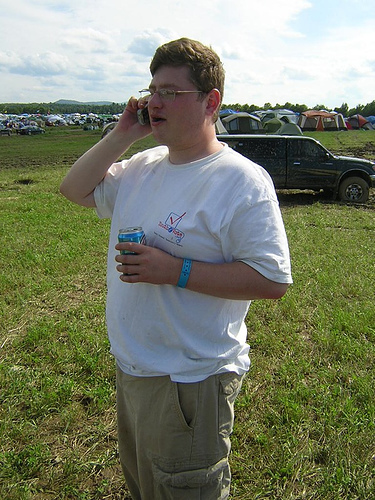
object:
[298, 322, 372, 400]
grass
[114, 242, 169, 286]
hand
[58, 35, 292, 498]
man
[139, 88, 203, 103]
glasses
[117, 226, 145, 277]
can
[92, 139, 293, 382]
shirt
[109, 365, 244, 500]
pants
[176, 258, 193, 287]
wrist band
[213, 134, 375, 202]
truck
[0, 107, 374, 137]
tents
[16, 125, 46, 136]
car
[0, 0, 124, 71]
cloud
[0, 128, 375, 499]
grass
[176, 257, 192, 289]
watch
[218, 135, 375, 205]
car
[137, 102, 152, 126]
cellphone